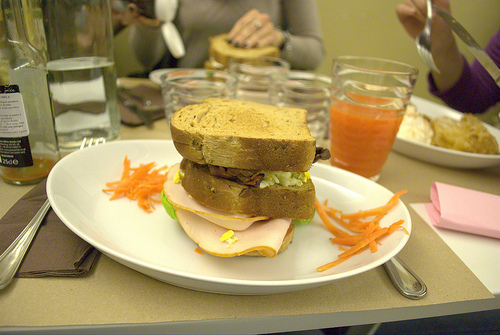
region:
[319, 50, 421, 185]
carrot juice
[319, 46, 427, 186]
round ridged glass holding carrot juice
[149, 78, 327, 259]
sandwich+a half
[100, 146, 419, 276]
shredded carrots to match the juice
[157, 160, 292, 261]
turkey or tofurky cold cut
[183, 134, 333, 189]
i hate to think this, but it's probably _real_ roast beef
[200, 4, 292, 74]
woman wearing ring holds bread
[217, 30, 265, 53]
dark fingernails, green - grey - black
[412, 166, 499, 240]
a pink paper rolled up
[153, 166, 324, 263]
innocent, glorious shredded lettuce, mixed up in animal parts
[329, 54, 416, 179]
a clear glass filled with an orange beverage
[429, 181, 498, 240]
a pink piece of paper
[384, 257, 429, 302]
The handle end of a piece of cutlery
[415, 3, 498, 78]
a fork and a knife being held by a person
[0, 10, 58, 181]
an empty wine bottle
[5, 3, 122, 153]
a clear pitcher filled half-way with water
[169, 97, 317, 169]
a thick piece of toasted bread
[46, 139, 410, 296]
a round white plate for the sandwich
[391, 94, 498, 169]
a plate full of food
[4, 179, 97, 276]
a brown napkin under a fork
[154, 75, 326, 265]
triple decker sandwhich with turkey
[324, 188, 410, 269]
carrots on a white plate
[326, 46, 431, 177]
tomato juice in a clear glass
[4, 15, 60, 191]
empty bottle on the table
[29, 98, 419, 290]
sandwhich on a white plate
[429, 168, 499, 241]
pink sheet of paper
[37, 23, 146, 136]
glass bottle with clear liquid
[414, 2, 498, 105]
fork and knife in a hand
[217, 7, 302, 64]
female hand on bread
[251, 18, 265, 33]
ring on a woman's hand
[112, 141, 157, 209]
shaved carrots on a plate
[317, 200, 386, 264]
shaved carrots on a plate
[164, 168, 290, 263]
lunch meat on a sandwhich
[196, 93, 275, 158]
toasted bread on a sandwhich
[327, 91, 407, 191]
orange juice in a glass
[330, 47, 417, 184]
carrot juice in a glass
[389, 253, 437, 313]
silver bottom of a utensil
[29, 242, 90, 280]
brown folded napkin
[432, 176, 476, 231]
pink folded paper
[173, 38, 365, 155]
many empty glasses on the table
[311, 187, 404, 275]
a group of orange carrot shavings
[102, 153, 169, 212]
a group of orange carrot shavings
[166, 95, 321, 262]
a bread and meat sandwich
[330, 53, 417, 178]
a clear drinking glass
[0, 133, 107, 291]
a silver fork utensil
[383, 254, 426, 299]
a silver eating utensil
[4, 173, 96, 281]
a brown paper napkin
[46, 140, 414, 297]
a white dinner plate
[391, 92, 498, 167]
a white dinner plate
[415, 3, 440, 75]
a silver fork utensil